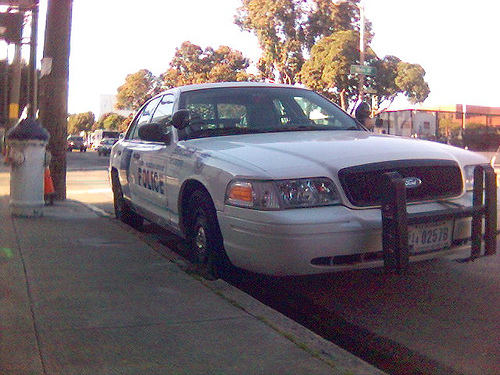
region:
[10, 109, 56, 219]
a blue and white fire hydrant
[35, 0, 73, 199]
a tall brown pole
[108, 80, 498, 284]
a white police car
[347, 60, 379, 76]
a green and white street sign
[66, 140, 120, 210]
part of a road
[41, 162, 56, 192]
a small orange cone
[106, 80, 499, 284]
There is a white police car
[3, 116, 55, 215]
there is a white and blue fire hydrant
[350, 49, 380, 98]
there is a street sign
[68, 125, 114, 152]
there are cars driving behind the police car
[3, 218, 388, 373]
there is a cement sidewalk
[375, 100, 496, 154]
there is a large white building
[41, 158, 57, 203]
there is an orange pylon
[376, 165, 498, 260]
the police car has a batting ram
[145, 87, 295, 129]
there is a caged enclosure in the back of the police car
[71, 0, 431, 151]
there are tall trees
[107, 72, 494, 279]
white police car parked on street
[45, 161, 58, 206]
orange cone on the sidewalk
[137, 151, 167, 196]
lettering on the police car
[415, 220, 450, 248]
license plate on front of police car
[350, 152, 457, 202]
front grill on police car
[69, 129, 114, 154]
cars driving down the road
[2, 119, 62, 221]
fire hydrant on the sidewalk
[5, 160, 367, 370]
sidewalk beside police car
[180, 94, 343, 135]
windshield of police car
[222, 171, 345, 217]
a headlight on a cop car.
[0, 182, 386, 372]
a sidewalk near a police car.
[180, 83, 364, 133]
the windshield on a car.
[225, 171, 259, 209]
right blinker on a cop car.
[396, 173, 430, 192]
a small ford emblem.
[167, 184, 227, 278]
Right front tire of a cop car.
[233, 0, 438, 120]
A tall leafy green tree.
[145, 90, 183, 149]
Passenger side window of a cop car.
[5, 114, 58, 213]
A trash can on a sidewalk.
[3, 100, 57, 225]
a white fire hydrant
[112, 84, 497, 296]
a police car by a curbside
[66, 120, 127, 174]
cars driving down a road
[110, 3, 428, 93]
tree tops on a sunny day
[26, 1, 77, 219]
a phone pole by a street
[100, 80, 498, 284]
a white police car with no lights on the top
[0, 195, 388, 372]
a sidewalk by a street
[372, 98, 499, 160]
a fence surrounding a court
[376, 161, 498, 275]
a cage in front of a car grill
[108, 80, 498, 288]
white car parked by the curb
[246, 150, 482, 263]
front of the white car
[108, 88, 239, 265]
white car's right side